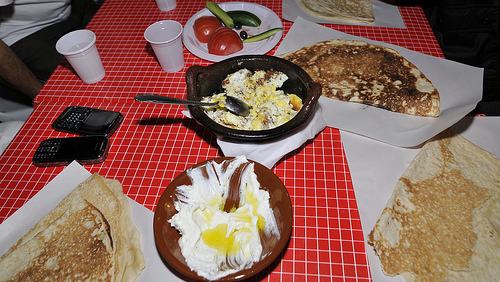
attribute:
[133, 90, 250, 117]
spoon — silver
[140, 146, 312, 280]
plate — round, brown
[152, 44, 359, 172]
skillet — black, cast-iron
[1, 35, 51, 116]
arm — black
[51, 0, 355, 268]
table cloth — checkered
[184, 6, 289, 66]
plate — White 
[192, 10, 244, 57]
tomato — Sliced